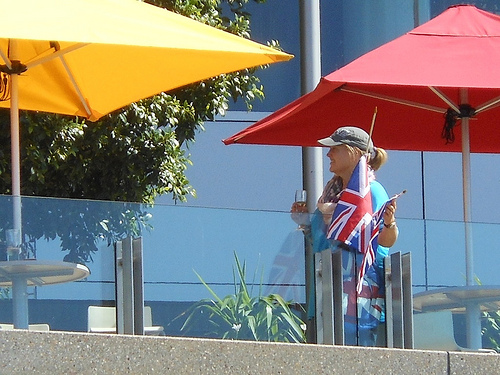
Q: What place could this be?
A: It is a patio.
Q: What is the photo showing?
A: It is showing a patio.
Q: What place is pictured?
A: It is a patio.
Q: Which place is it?
A: It is a patio.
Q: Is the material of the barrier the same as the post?
A: No, the barrier is made of glass and the post is made of metal.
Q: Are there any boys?
A: No, there are no boys.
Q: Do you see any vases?
A: No, there are no vases.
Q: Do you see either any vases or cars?
A: No, there are no vases or cars.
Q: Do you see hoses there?
A: No, there are no hoses.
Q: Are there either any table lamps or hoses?
A: No, there are no hoses or table lamps.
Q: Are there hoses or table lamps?
A: No, there are no hoses or table lamps.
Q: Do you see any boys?
A: No, there are no boys.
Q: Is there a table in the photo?
A: Yes, there is a table.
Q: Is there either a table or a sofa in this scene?
A: Yes, there is a table.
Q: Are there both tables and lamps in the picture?
A: No, there is a table but no lamps.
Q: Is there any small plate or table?
A: Yes, there is a small table.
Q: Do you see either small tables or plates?
A: Yes, there is a small table.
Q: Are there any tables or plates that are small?
A: Yes, the table is small.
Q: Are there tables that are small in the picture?
A: Yes, there is a small table.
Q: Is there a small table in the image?
A: Yes, there is a small table.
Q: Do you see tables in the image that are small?
A: Yes, there is a table that is small.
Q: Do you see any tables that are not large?
A: Yes, there is a small table.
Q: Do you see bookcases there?
A: No, there are no bookcases.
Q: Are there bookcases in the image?
A: No, there are no bookcases.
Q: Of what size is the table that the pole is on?
A: The table is small.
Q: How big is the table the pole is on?
A: The table is small.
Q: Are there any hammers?
A: No, there are no hammers.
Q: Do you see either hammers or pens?
A: No, there are no hammers or pens.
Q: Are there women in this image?
A: Yes, there is a woman.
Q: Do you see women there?
A: Yes, there is a woman.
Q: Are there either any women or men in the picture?
A: Yes, there is a woman.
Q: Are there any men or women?
A: Yes, there is a woman.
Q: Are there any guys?
A: No, there are no guys.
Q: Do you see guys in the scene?
A: No, there are no guys.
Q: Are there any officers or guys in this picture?
A: No, there are no guys or officers.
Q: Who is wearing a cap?
A: The woman is wearing a cap.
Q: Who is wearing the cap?
A: The woman is wearing a cap.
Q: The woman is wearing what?
A: The woman is wearing a cap.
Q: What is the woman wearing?
A: The woman is wearing a cap.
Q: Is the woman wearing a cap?
A: Yes, the woman is wearing a cap.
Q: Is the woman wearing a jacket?
A: No, the woman is wearing a cap.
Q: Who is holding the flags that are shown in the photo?
A: The woman is holding the flags.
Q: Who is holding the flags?
A: The woman is holding the flags.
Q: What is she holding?
A: The woman is holding the flags.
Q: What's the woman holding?
A: The woman is holding the flags.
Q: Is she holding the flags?
A: Yes, the woman is holding the flags.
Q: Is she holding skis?
A: No, the woman is holding the flags.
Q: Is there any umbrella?
A: Yes, there is an umbrella.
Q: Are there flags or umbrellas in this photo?
A: Yes, there is an umbrella.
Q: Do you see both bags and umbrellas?
A: No, there is an umbrella but no bags.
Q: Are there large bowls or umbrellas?
A: Yes, there is a large umbrella.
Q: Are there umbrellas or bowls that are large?
A: Yes, the umbrella is large.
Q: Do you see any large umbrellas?
A: Yes, there is a large umbrella.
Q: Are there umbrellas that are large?
A: Yes, there is an umbrella that is large.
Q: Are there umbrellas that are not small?
A: Yes, there is a large umbrella.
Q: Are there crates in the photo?
A: No, there are no crates.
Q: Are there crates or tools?
A: No, there are no crates or tools.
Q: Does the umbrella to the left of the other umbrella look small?
A: No, the umbrella is large.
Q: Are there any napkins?
A: No, there are no napkins.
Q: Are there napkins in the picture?
A: No, there are no napkins.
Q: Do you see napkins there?
A: No, there are no napkins.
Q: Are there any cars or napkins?
A: No, there are no napkins or cars.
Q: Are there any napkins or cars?
A: No, there are no napkins or cars.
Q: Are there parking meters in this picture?
A: No, there are no parking meters.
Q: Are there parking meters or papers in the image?
A: No, there are no parking meters or papers.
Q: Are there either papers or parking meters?
A: No, there are no parking meters or papers.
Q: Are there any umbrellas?
A: Yes, there is an umbrella.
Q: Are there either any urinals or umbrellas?
A: Yes, there is an umbrella.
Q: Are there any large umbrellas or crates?
A: Yes, there is a large umbrella.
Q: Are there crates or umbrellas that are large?
A: Yes, the umbrella is large.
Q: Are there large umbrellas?
A: Yes, there is a large umbrella.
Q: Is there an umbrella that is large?
A: Yes, there is an umbrella that is large.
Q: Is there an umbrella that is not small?
A: Yes, there is a large umbrella.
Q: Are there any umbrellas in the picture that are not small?
A: Yes, there is a large umbrella.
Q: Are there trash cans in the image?
A: No, there are no trash cans.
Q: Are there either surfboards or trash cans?
A: No, there are no trash cans or surfboards.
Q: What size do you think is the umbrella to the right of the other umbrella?
A: The umbrella is large.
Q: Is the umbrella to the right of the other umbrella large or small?
A: The umbrella is large.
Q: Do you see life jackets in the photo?
A: No, there are no life jackets.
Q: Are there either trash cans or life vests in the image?
A: No, there are no life vests or trash cans.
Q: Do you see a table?
A: Yes, there is a table.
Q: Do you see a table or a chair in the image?
A: Yes, there is a table.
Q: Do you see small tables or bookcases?
A: Yes, there is a small table.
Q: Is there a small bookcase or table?
A: Yes, there is a small table.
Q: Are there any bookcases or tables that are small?
A: Yes, the table is small.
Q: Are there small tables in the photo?
A: Yes, there is a small table.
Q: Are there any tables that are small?
A: Yes, there is a table that is small.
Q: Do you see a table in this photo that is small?
A: Yes, there is a table that is small.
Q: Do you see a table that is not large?
A: Yes, there is a small table.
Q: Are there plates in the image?
A: No, there are no plates.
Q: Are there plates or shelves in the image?
A: No, there are no plates or shelves.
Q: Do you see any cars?
A: No, there are no cars.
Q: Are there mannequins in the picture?
A: No, there are no mannequins.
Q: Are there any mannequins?
A: No, there are no mannequins.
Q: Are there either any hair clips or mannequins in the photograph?
A: No, there are no mannequins or hair clips.